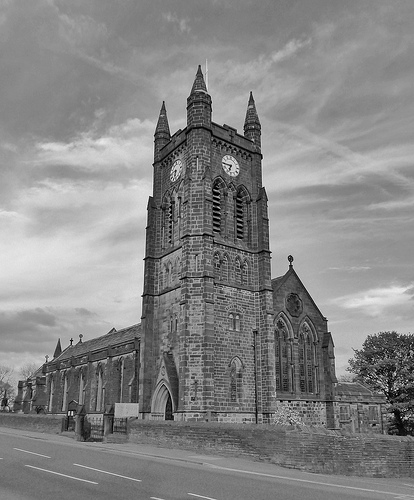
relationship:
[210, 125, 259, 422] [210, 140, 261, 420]
wall made of bricks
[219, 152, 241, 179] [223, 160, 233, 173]
clock says 6:45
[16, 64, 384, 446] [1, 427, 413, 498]
building by side of road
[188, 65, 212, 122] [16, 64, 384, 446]
spire on top of building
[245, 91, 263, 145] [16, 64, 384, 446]
spire on top of building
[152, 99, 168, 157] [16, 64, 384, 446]
spire on top of building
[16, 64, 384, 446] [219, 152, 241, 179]
building has clock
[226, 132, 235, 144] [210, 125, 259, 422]
cross on wall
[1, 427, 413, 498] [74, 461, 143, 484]
road has stripe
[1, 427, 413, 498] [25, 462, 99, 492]
road has stripe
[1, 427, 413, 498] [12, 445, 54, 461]
road has stripe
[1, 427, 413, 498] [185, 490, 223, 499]
road has stripe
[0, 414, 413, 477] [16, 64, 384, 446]
brick wall surrounding building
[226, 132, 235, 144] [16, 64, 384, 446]
cross on building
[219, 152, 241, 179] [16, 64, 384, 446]
clock on building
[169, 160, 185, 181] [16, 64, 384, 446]
clock on building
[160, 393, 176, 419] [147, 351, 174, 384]
door has arch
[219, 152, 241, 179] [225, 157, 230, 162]
clock has roman numerals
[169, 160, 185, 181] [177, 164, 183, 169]
clock has roman numerals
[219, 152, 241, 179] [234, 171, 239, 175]
clock has roman numerals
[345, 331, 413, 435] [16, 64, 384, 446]
tree on right side of building